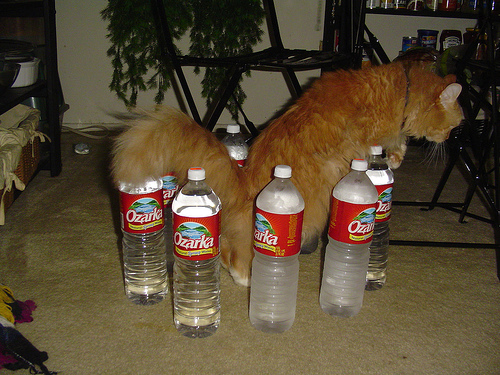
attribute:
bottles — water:
[167, 167, 376, 342]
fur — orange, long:
[107, 57, 462, 289]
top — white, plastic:
[272, 164, 294, 179]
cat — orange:
[104, 56, 465, 264]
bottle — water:
[319, 159, 378, 317]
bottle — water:
[116, 181, 170, 304]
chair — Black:
[148, 0, 358, 135]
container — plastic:
[415, 26, 440, 51]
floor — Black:
[49, 92, 499, 362]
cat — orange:
[109, 61, 466, 286]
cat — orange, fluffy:
[288, 56, 453, 194]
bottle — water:
[251, 165, 301, 330]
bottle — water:
[360, 144, 395, 289]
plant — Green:
[87, 0, 268, 161]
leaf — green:
[152, 44, 165, 56]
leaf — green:
[116, 89, 127, 102]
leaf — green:
[109, 75, 121, 91]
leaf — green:
[143, 76, 156, 87]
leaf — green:
[134, 5, 147, 24]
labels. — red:
[250, 205, 306, 262]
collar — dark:
[401, 58, 411, 110]